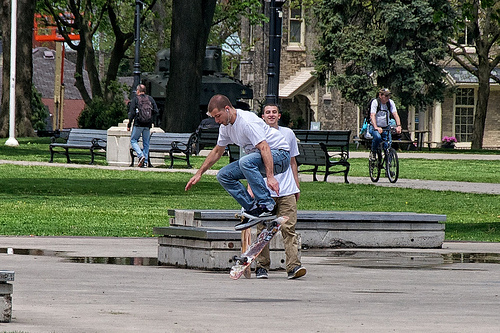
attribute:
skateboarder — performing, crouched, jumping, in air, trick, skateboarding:
[178, 93, 301, 231]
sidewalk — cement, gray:
[1, 154, 500, 202]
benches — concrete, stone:
[166, 201, 449, 254]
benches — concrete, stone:
[148, 219, 311, 273]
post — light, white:
[3, 1, 23, 152]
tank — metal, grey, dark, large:
[131, 38, 260, 158]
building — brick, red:
[24, 44, 113, 136]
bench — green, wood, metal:
[43, 118, 120, 165]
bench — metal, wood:
[127, 123, 197, 173]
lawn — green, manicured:
[3, 123, 499, 244]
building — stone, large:
[235, 0, 499, 162]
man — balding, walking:
[123, 81, 154, 174]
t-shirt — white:
[212, 105, 293, 158]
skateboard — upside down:
[223, 209, 294, 282]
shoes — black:
[241, 199, 278, 226]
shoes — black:
[233, 201, 264, 232]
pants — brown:
[239, 185, 308, 275]